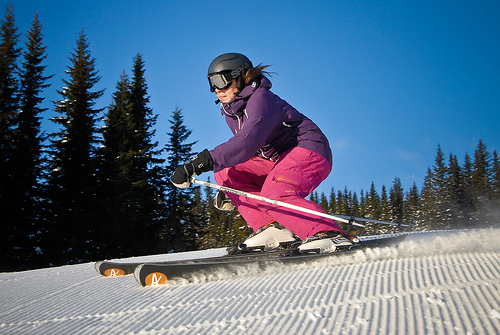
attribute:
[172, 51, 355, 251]
girl — skiing, leaning, bent, skier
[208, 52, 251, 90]
helmet — worn, grey, black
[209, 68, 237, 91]
goggles — black, ski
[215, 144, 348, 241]
pants — pink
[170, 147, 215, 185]
gloves — black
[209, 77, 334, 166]
jacket — purple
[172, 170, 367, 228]
pole — white, ski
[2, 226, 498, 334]
snow — packed, coming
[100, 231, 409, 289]
skis — pair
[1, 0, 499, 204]
sky — blue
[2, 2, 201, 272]
trees — green, tall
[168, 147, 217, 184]
glove — black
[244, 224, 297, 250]
boot — white